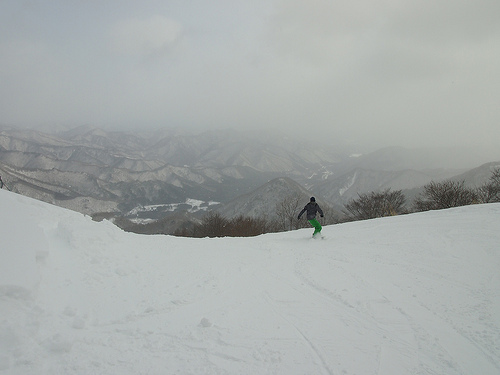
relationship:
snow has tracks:
[3, 189, 497, 372] [278, 321, 336, 374]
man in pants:
[294, 194, 326, 240] [308, 216, 322, 235]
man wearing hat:
[294, 194, 326, 240] [311, 195, 317, 202]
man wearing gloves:
[294, 194, 326, 240] [294, 215, 301, 220]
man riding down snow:
[294, 194, 326, 240] [3, 189, 497, 372]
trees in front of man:
[341, 187, 410, 221] [294, 194, 326, 240]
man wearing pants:
[294, 194, 326, 240] [308, 216, 322, 235]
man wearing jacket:
[294, 194, 326, 240] [297, 201, 325, 219]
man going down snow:
[294, 194, 326, 240] [3, 189, 497, 372]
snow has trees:
[3, 189, 497, 372] [341, 187, 410, 221]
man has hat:
[294, 194, 326, 240] [311, 195, 317, 202]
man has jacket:
[294, 194, 326, 240] [297, 201, 325, 219]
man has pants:
[294, 194, 326, 240] [308, 216, 322, 235]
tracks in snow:
[278, 321, 336, 374] [3, 189, 497, 372]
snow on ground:
[3, 189, 497, 372] [29, 231, 472, 356]